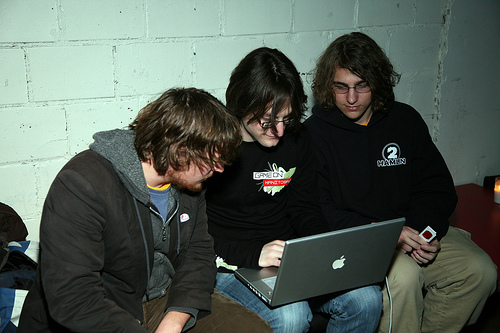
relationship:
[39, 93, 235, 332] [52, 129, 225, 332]
man wears hoody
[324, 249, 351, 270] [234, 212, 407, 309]
logo on laptop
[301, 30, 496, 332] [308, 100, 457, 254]
boy wears hoody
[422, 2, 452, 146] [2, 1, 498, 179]
crack in wall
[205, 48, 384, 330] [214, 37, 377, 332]
man in middle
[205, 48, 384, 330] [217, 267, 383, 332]
man wears jeans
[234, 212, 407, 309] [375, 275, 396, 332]
laptop has power cord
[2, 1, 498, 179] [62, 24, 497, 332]
wall behind people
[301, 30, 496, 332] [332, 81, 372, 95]
person wears glasses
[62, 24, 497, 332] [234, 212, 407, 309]
men looking at computer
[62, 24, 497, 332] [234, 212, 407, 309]
men looking at laptop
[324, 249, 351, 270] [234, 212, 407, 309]
logo on back of computer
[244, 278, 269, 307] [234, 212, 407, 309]
ports on computer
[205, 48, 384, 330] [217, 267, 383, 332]
man wearing jeans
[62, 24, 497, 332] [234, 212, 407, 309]
boys looking at laptop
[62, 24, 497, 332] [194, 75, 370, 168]
men wearing eye glasses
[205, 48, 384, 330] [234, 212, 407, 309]
man holds laptop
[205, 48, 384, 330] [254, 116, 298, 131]
man wears eye glasses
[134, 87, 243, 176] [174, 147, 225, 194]
hair on face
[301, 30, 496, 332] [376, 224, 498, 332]
man wears pants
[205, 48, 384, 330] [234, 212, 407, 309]
guy types on laptop